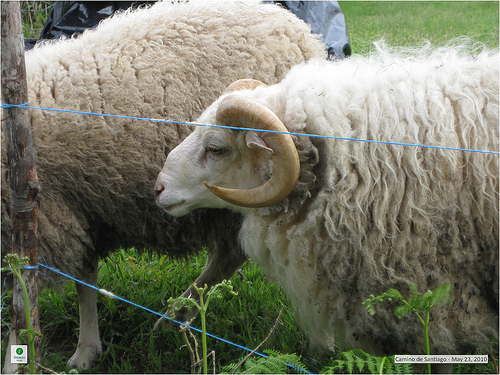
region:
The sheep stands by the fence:
[142, 77, 487, 337]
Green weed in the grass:
[340, 288, 418, 362]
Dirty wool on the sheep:
[319, 218, 430, 360]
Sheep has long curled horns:
[194, 75, 308, 229]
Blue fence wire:
[0, 87, 496, 192]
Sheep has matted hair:
[43, 30, 207, 184]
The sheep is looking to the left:
[124, 99, 496, 274]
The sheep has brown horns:
[202, 74, 358, 279]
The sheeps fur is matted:
[308, 227, 424, 347]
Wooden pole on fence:
[2, 10, 60, 300]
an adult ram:
[155, 47, 498, 359]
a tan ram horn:
[209, 97, 295, 209]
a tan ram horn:
[221, 79, 256, 94]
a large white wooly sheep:
[0, 0, 335, 373]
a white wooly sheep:
[157, 42, 494, 371]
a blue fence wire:
[9, 92, 496, 164]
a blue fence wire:
[26, 248, 299, 369]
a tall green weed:
[168, 280, 238, 370]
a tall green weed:
[368, 280, 467, 373]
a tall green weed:
[4, 252, 44, 372]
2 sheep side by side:
[4, 14, 434, 274]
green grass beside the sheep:
[25, 251, 473, 330]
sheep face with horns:
[137, 81, 355, 231]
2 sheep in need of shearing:
[36, 39, 496, 314]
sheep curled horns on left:
[201, 99, 314, 214]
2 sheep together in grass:
[26, 38, 466, 300]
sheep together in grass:
[41, 65, 391, 190]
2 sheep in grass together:
[20, 46, 473, 283]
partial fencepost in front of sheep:
[1, 185, 41, 190]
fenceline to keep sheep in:
[11, 211, 331, 322]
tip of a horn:
[191, 167, 237, 209]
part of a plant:
[402, 292, 438, 344]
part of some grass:
[236, 293, 276, 335]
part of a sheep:
[382, 183, 444, 250]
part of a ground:
[223, 268, 260, 304]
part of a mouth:
[150, 182, 202, 239]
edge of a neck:
[198, 197, 229, 223]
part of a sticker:
[3, 336, 24, 359]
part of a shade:
[125, 320, 177, 368]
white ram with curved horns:
[153, 91, 315, 212]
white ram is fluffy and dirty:
[325, 79, 469, 235]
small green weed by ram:
[371, 259, 491, 351]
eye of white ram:
[196, 123, 231, 190]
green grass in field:
[365, 19, 460, 34]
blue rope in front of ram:
[136, 280, 264, 342]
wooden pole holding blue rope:
[1, 27, 61, 183]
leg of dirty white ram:
[41, 255, 133, 360]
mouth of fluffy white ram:
[158, 189, 185, 226]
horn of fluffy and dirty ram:
[211, 102, 336, 219]